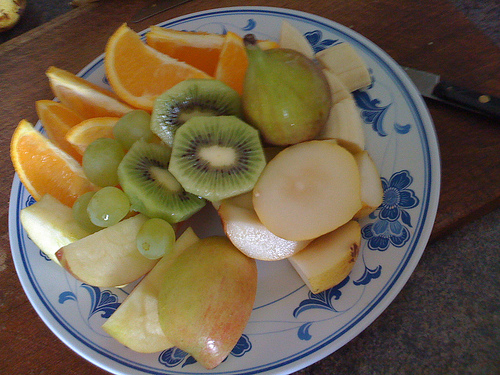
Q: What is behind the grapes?
A: Oranges.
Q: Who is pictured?
A: No one.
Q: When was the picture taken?
A: Meal time.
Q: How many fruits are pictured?
A: 7.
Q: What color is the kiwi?
A: Green.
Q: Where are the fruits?
A: On a plate.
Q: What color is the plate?
A: Blue and white.